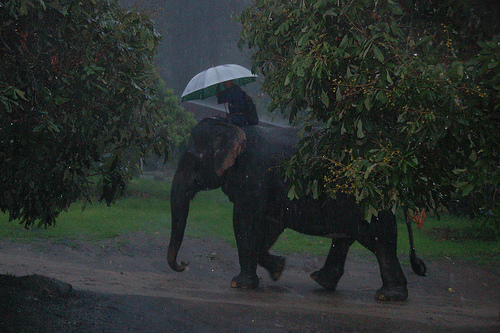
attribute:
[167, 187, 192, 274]
trunk — long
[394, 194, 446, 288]
tail — long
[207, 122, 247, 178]
ears — brown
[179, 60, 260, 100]
umbrella —  white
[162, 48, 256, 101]
umbrella — blue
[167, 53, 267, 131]
umbrella — light blue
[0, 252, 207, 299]
puddle — muddy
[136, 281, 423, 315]
stream — muddy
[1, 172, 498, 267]
grass — green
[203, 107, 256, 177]
ear — big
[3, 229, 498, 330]
pathway — muddy